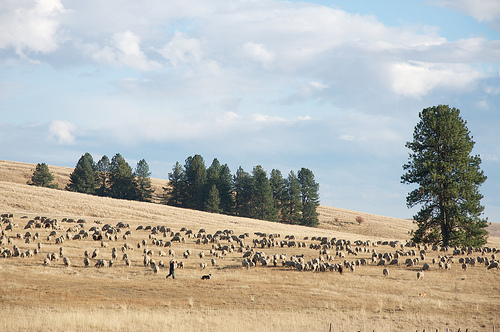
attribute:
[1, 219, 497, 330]
field — dry, dead, yellow, wispy, bare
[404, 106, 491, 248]
tree — tall, behind, green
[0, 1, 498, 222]
sky — blue, cloudy